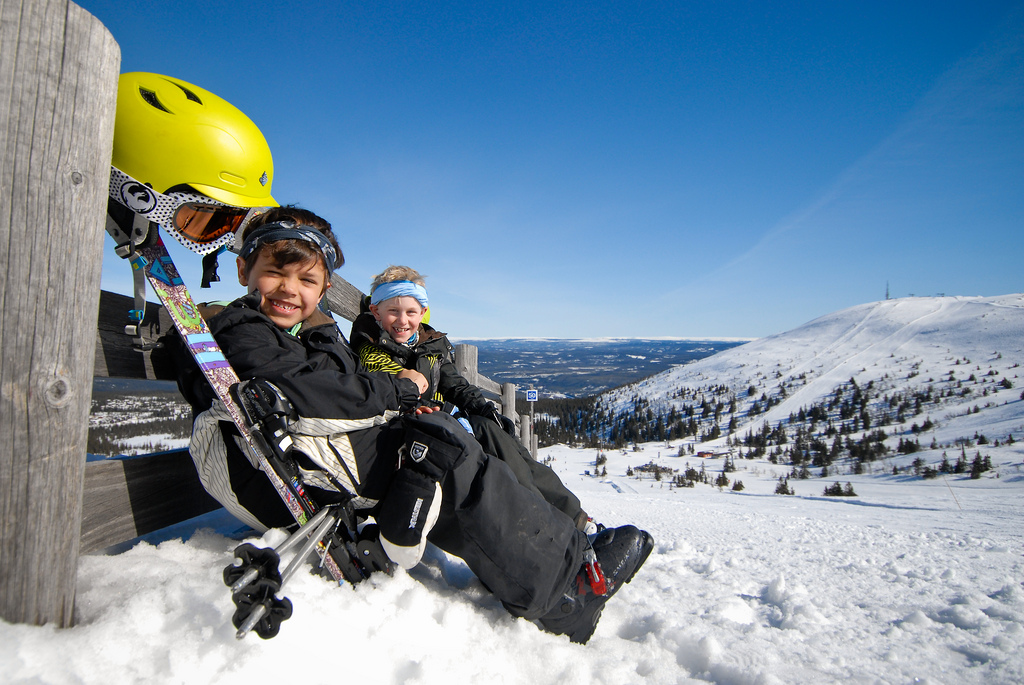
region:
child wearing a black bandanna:
[231, 209, 346, 271]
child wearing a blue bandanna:
[359, 279, 429, 300]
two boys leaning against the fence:
[204, 161, 669, 629]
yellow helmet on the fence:
[94, 64, 285, 254]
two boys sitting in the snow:
[185, 189, 682, 646]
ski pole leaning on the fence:
[113, 241, 358, 571]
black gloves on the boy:
[338, 389, 495, 558]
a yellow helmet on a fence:
[115, 54, 262, 255]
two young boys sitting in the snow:
[215, 193, 630, 630]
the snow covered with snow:
[705, 500, 934, 656]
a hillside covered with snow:
[683, 310, 982, 482]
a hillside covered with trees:
[779, 360, 991, 485]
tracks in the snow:
[700, 510, 999, 646]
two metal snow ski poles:
[234, 484, 349, 633]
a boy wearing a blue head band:
[365, 283, 436, 302]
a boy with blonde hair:
[377, 260, 447, 330]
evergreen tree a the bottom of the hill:
[841, 470, 854, 499]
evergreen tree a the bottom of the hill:
[719, 449, 738, 479]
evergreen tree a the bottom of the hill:
[740, 420, 754, 455]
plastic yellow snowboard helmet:
[115, 63, 278, 225]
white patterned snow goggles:
[127, 174, 254, 247]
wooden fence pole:
[5, 3, 120, 681]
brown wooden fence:
[4, 10, 649, 640]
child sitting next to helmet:
[200, 206, 663, 658]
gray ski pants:
[354, 385, 634, 648]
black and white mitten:
[362, 399, 470, 576]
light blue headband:
[368, 279, 435, 308]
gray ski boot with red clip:
[544, 495, 656, 658]